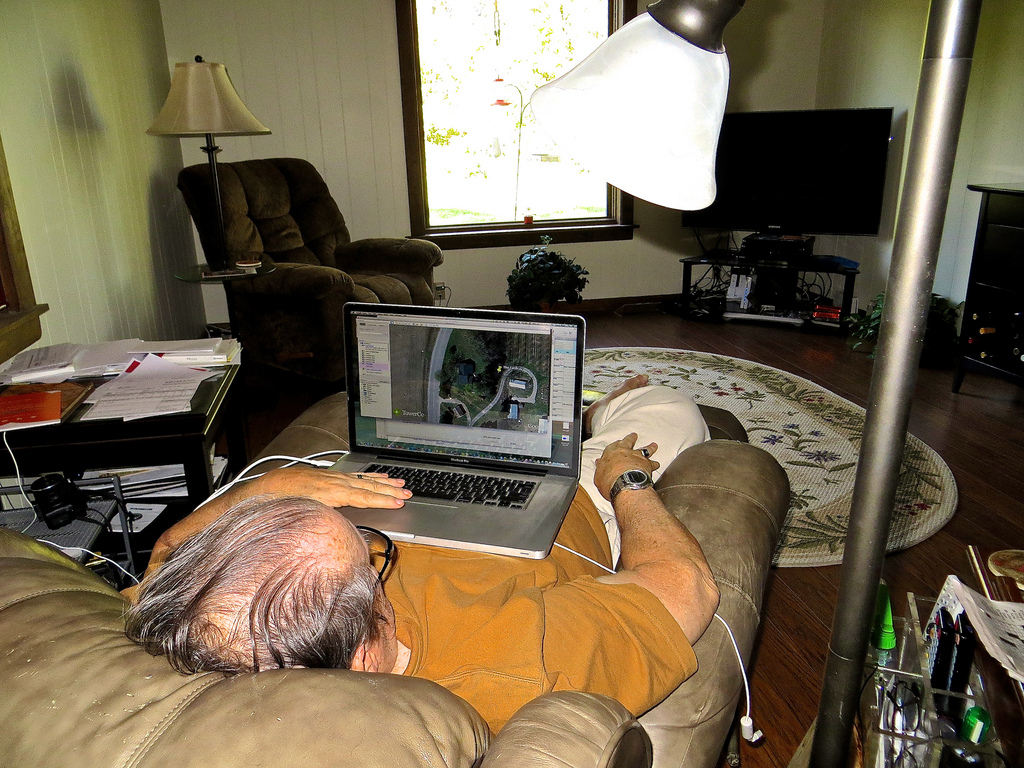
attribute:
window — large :
[399, 0, 627, 251]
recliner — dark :
[175, 146, 447, 390]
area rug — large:
[559, 339, 958, 581]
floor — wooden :
[575, 308, 1022, 762]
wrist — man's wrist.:
[606, 461, 661, 501]